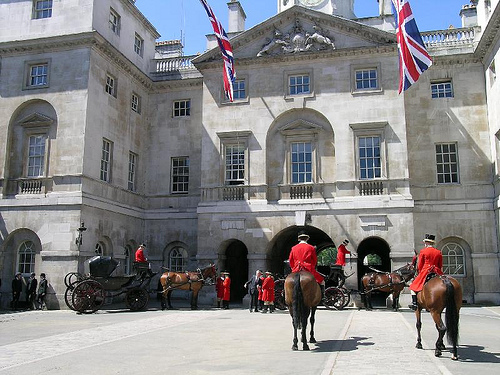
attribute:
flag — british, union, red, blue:
[386, 1, 442, 100]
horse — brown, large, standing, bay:
[156, 259, 221, 310]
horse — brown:
[278, 264, 322, 354]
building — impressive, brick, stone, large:
[3, 1, 500, 313]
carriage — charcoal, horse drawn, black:
[64, 254, 160, 313]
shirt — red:
[131, 248, 150, 261]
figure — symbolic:
[253, 21, 341, 61]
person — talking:
[257, 267, 278, 316]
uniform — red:
[407, 246, 453, 296]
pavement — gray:
[4, 299, 500, 375]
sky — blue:
[135, 1, 476, 57]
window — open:
[223, 137, 249, 203]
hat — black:
[419, 231, 439, 245]